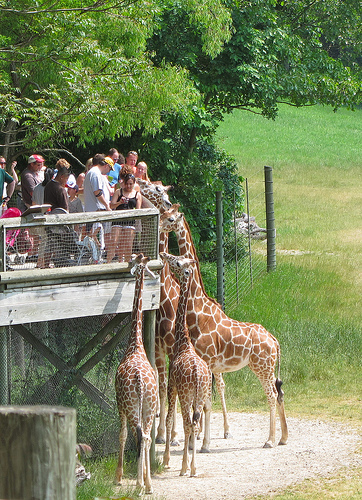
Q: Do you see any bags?
A: No, there are no bags.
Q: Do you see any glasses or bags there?
A: No, there are no bags or glasses.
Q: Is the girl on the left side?
A: Yes, the girl is on the left of the image.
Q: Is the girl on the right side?
A: No, the girl is on the left of the image.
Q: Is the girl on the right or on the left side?
A: The girl is on the left of the image.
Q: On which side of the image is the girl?
A: The girl is on the left of the image.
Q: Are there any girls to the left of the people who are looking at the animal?
A: Yes, there is a girl to the left of the people.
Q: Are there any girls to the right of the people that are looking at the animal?
A: No, the girl is to the left of the people.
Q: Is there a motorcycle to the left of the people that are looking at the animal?
A: No, there is a girl to the left of the people.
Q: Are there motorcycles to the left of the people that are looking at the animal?
A: No, there is a girl to the left of the people.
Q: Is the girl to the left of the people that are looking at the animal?
A: Yes, the girl is to the left of the people.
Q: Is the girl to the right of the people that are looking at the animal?
A: No, the girl is to the left of the people.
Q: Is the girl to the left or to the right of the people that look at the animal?
A: The girl is to the left of the people.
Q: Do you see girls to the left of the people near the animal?
A: Yes, there is a girl to the left of the people.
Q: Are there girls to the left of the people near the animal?
A: Yes, there is a girl to the left of the people.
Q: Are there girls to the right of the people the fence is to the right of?
A: No, the girl is to the left of the people.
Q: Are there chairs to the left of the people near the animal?
A: No, there is a girl to the left of the people.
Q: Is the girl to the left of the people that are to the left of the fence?
A: Yes, the girl is to the left of the people.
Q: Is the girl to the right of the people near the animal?
A: No, the girl is to the left of the people.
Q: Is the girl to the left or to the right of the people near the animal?
A: The girl is to the left of the people.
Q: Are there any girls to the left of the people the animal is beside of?
A: Yes, there is a girl to the left of the people.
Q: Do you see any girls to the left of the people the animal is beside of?
A: Yes, there is a girl to the left of the people.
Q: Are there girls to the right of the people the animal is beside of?
A: No, the girl is to the left of the people.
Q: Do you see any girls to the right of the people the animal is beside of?
A: No, the girl is to the left of the people.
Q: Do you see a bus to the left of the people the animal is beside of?
A: No, there is a girl to the left of the people.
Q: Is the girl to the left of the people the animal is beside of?
A: Yes, the girl is to the left of the people.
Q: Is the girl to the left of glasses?
A: No, the girl is to the left of the people.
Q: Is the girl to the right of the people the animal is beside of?
A: No, the girl is to the left of the people.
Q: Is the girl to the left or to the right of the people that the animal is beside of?
A: The girl is to the left of the people.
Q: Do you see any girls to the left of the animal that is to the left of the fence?
A: Yes, there is a girl to the left of the animal.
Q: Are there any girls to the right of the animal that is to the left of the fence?
A: No, the girl is to the left of the animal.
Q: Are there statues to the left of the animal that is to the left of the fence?
A: No, there is a girl to the left of the animal.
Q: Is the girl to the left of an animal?
A: Yes, the girl is to the left of an animal.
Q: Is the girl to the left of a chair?
A: No, the girl is to the left of an animal.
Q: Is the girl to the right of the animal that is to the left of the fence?
A: No, the girl is to the left of the animal.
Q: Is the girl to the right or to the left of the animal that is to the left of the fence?
A: The girl is to the left of the animal.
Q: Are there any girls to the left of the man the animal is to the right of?
A: Yes, there is a girl to the left of the man.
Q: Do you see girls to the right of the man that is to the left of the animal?
A: No, the girl is to the left of the man.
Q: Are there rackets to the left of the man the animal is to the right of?
A: No, there is a girl to the left of the man.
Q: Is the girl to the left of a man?
A: Yes, the girl is to the left of a man.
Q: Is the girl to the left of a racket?
A: No, the girl is to the left of a man.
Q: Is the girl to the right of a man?
A: No, the girl is to the left of a man.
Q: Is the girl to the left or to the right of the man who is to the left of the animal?
A: The girl is to the left of the man.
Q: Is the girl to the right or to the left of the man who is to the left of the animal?
A: The girl is to the left of the man.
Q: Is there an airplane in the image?
A: No, there are no airplanes.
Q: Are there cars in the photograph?
A: No, there are no cars.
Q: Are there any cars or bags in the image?
A: No, there are no cars or bags.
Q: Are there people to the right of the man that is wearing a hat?
A: Yes, there are people to the right of the man.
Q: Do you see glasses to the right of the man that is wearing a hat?
A: No, there are people to the right of the man.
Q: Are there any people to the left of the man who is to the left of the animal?
A: Yes, there are people to the left of the man.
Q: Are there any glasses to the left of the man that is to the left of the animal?
A: No, there are people to the left of the man.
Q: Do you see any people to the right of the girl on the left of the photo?
A: Yes, there are people to the right of the girl.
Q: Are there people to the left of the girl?
A: No, the people are to the right of the girl.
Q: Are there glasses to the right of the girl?
A: No, there are people to the right of the girl.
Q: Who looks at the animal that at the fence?
A: The people look at the animal.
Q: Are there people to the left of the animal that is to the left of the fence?
A: Yes, there are people to the left of the animal.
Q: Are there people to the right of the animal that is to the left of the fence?
A: No, the people are to the left of the animal.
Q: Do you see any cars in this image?
A: No, there are no cars.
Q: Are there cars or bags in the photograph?
A: No, there are no cars or bags.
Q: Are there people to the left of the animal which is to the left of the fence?
A: Yes, there are people to the left of the animal.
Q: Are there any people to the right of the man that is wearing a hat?
A: Yes, there are people to the right of the man.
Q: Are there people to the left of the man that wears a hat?
A: No, the people are to the right of the man.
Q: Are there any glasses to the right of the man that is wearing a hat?
A: No, there are people to the right of the man.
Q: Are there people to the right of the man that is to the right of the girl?
A: Yes, there are people to the right of the man.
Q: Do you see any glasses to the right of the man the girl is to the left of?
A: No, there are people to the right of the man.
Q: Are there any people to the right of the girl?
A: Yes, there are people to the right of the girl.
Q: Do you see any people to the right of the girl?
A: Yes, there are people to the right of the girl.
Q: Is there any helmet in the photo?
A: No, there are no helmets.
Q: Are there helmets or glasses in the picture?
A: No, there are no helmets or glasses.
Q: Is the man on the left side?
A: Yes, the man is on the left of the image.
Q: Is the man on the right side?
A: No, the man is on the left of the image.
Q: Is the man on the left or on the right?
A: The man is on the left of the image.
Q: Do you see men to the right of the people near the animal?
A: No, the man is to the left of the people.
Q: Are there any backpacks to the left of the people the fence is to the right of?
A: No, there is a man to the left of the people.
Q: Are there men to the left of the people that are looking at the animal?
A: Yes, there is a man to the left of the people.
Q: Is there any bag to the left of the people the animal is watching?
A: No, there is a man to the left of the people.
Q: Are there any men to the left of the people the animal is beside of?
A: Yes, there is a man to the left of the people.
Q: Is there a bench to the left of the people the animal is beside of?
A: No, there is a man to the left of the people.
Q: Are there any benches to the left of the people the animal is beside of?
A: No, there is a man to the left of the people.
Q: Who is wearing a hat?
A: The man is wearing a hat.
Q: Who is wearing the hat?
A: The man is wearing a hat.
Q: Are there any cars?
A: No, there are no cars.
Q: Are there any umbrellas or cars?
A: No, there are no cars or umbrellas.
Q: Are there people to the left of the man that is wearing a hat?
A: No, the people are to the right of the man.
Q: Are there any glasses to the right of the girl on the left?
A: No, there are people to the right of the girl.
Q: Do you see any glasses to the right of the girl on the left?
A: No, there are people to the right of the girl.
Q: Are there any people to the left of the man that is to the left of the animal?
A: Yes, there are people to the left of the man.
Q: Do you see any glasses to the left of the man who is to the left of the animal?
A: No, there are people to the left of the man.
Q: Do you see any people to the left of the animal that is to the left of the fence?
A: Yes, there are people to the left of the animal.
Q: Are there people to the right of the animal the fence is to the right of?
A: No, the people are to the left of the animal.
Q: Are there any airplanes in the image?
A: No, there are no airplanes.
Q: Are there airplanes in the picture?
A: No, there are no airplanes.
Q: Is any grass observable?
A: Yes, there is grass.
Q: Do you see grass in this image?
A: Yes, there is grass.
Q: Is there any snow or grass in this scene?
A: Yes, there is grass.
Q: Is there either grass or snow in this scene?
A: Yes, there is grass.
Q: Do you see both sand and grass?
A: No, there is grass but no sand.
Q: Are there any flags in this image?
A: No, there are no flags.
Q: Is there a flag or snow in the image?
A: No, there are no flags or snow.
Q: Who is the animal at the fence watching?
A: The animal is watching the people.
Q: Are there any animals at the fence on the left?
A: Yes, there is an animal at the fence.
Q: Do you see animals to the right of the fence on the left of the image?
A: Yes, there is an animal to the right of the fence.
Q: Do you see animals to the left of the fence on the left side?
A: No, the animal is to the right of the fence.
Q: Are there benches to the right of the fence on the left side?
A: No, there is an animal to the right of the fence.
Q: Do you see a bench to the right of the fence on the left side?
A: No, there is an animal to the right of the fence.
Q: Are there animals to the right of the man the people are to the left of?
A: Yes, there is an animal to the right of the man.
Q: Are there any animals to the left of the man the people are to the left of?
A: No, the animal is to the right of the man.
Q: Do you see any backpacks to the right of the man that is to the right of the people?
A: No, there is an animal to the right of the man.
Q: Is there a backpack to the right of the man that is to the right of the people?
A: No, there is an animal to the right of the man.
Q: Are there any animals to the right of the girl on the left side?
A: Yes, there is an animal to the right of the girl.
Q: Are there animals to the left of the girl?
A: No, the animal is to the right of the girl.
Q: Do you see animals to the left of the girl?
A: No, the animal is to the right of the girl.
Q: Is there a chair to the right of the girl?
A: No, there is an animal to the right of the girl.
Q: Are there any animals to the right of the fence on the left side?
A: Yes, there is an animal to the right of the fence.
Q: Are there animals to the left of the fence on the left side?
A: No, the animal is to the right of the fence.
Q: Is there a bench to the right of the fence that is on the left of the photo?
A: No, there is an animal to the right of the fence.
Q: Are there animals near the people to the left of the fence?
A: Yes, there is an animal near the people.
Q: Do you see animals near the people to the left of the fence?
A: Yes, there is an animal near the people.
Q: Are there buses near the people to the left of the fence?
A: No, there is an animal near the people.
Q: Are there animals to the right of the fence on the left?
A: Yes, there is an animal to the right of the fence.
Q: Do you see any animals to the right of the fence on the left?
A: Yes, there is an animal to the right of the fence.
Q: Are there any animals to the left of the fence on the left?
A: No, the animal is to the right of the fence.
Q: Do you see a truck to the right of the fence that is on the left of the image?
A: No, there is an animal to the right of the fence.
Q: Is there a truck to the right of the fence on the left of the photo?
A: No, there is an animal to the right of the fence.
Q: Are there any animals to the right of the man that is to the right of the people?
A: Yes, there is an animal to the right of the man.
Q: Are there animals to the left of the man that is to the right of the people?
A: No, the animal is to the right of the man.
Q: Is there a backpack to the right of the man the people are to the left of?
A: No, there is an animal to the right of the man.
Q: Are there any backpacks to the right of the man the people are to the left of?
A: No, there is an animal to the right of the man.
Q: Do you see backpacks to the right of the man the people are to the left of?
A: No, there is an animal to the right of the man.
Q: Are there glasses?
A: No, there are no glasses.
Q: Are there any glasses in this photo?
A: No, there are no glasses.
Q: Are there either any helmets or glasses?
A: No, there are no glasses or helmets.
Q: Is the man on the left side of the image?
A: Yes, the man is on the left of the image.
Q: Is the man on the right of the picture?
A: No, the man is on the left of the image.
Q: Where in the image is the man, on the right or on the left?
A: The man is on the left of the image.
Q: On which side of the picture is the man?
A: The man is on the left of the image.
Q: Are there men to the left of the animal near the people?
A: Yes, there is a man to the left of the animal.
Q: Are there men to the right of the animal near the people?
A: No, the man is to the left of the animal.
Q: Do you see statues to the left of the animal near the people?
A: No, there is a man to the left of the animal.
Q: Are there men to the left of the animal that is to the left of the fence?
A: Yes, there is a man to the left of the animal.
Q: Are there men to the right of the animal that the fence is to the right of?
A: No, the man is to the left of the animal.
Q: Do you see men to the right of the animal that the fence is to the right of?
A: No, the man is to the left of the animal.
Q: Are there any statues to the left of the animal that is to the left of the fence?
A: No, there is a man to the left of the animal.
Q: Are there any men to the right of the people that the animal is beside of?
A: Yes, there is a man to the right of the people.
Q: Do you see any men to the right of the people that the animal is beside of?
A: Yes, there is a man to the right of the people.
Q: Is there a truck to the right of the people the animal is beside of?
A: No, there is a man to the right of the people.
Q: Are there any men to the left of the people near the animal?
A: Yes, there is a man to the left of the people.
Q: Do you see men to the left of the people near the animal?
A: Yes, there is a man to the left of the people.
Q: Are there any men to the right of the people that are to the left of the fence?
A: No, the man is to the left of the people.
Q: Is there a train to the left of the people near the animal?
A: No, there is a man to the left of the people.